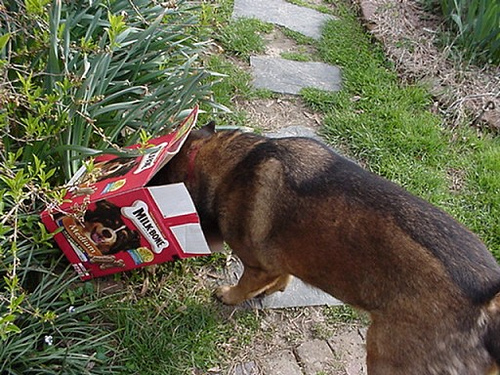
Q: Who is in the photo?
A: A dog.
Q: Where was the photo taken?
A: A yard.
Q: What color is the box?
A: Red.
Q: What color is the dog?
A: Brown.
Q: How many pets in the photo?
A: One.